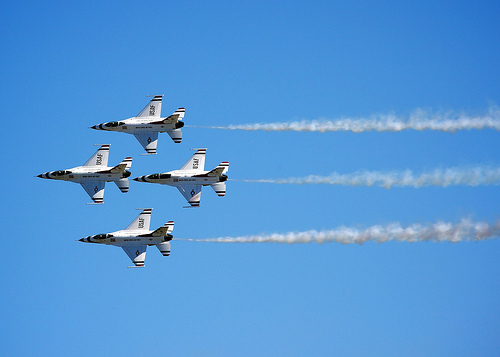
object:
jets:
[33, 95, 230, 269]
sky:
[1, 2, 500, 357]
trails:
[172, 101, 499, 246]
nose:
[37, 171, 51, 179]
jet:
[33, 144, 132, 205]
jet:
[87, 94, 186, 156]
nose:
[91, 122, 105, 130]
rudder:
[109, 164, 128, 174]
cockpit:
[52, 170, 72, 176]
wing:
[79, 180, 105, 203]